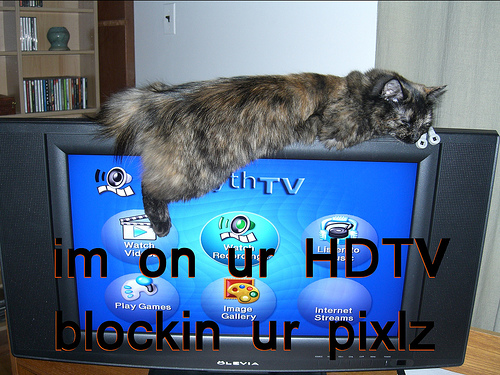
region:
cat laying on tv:
[88, 65, 453, 241]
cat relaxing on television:
[77, 63, 457, 239]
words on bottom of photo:
[41, 228, 461, 365]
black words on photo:
[45, 224, 460, 357]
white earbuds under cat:
[414, 123, 441, 153]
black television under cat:
[2, 110, 498, 374]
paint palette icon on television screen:
[226, 282, 261, 310]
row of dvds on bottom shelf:
[21, 74, 91, 114]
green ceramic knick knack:
[43, 22, 73, 57]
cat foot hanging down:
[132, 178, 178, 241]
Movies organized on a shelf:
[16, 15, 89, 110]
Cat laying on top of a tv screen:
[83, 67, 448, 237]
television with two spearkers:
[0, 122, 499, 371]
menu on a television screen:
[70, 156, 418, 346]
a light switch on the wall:
[162, 5, 177, 32]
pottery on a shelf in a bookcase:
[43, 25, 74, 52]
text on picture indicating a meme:
[53, 236, 450, 359]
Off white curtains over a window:
[375, 0, 498, 334]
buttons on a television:
[311, 352, 393, 362]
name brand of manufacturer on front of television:
[215, 359, 260, 366]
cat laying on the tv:
[93, 71, 441, 231]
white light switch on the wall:
[156, 1, 180, 29]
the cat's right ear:
[383, 75, 403, 107]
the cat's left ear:
[415, 80, 447, 102]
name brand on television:
[211, 353, 262, 371]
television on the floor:
[7, 118, 484, 372]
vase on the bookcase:
[48, 18, 77, 57]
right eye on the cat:
[392, 111, 412, 127]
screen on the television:
[69, 154, 408, 334]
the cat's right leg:
[145, 161, 190, 244]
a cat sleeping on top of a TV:
[100, 67, 446, 232]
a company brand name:
[215, 352, 260, 367]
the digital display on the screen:
[253, 160, 413, 335]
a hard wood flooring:
[470, 329, 499, 371]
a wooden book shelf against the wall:
[0, 0, 101, 118]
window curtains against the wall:
[444, 0, 499, 127]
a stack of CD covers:
[22, 74, 86, 111]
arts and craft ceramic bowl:
[45, 26, 72, 54]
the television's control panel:
[313, 350, 400, 371]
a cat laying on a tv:
[7, 1, 481, 366]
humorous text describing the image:
[27, 210, 493, 367]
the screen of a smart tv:
[63, 141, 402, 373]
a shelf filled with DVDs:
[20, 65, 104, 108]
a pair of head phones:
[391, 125, 456, 156]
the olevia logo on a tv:
[203, 350, 275, 372]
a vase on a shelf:
[50, 20, 83, 50]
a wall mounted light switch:
[159, 6, 190, 33]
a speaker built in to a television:
[443, 156, 498, 338]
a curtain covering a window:
[333, 3, 448, 60]